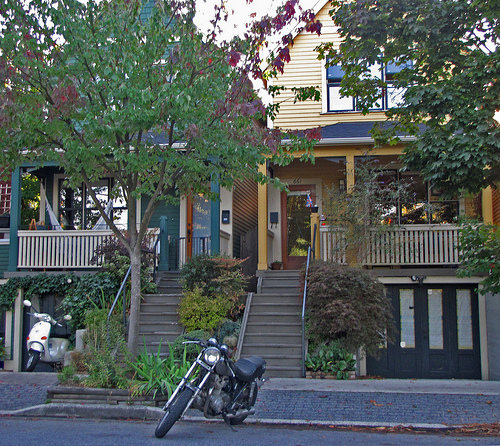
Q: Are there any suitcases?
A: No, there are no suitcases.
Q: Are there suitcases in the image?
A: No, there are no suitcases.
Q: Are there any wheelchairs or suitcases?
A: No, there are no suitcases or wheelchairs.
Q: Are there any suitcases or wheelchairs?
A: No, there are no suitcases or wheelchairs.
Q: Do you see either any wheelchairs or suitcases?
A: No, there are no suitcases or wheelchairs.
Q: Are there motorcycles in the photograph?
A: Yes, there is a motorcycle.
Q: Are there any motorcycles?
A: Yes, there is a motorcycle.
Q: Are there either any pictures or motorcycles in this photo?
A: Yes, there is a motorcycle.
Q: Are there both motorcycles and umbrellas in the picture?
A: No, there is a motorcycle but no umbrellas.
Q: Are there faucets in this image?
A: No, there are no faucets.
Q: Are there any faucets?
A: No, there are no faucets.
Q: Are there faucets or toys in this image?
A: No, there are no faucets or toys.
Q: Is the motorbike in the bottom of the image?
A: Yes, the motorbike is in the bottom of the image.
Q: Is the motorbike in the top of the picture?
A: No, the motorbike is in the bottom of the image.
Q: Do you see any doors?
A: Yes, there is a door.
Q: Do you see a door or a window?
A: Yes, there is a door.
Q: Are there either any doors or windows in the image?
A: Yes, there is a door.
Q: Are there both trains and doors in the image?
A: No, there is a door but no trains.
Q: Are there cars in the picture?
A: No, there are no cars.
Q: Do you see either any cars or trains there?
A: No, there are no cars or trains.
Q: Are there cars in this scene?
A: No, there are no cars.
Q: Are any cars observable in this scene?
A: No, there are no cars.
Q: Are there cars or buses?
A: No, there are no cars or buses.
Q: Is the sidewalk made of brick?
A: Yes, the sidewalk is made of brick.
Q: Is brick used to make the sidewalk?
A: Yes, the sidewalk is made of brick.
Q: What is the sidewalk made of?
A: The sidewalk is made of brick.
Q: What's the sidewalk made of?
A: The sidewalk is made of brick.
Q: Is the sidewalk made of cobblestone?
A: No, the sidewalk is made of brick.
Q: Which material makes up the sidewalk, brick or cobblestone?
A: The sidewalk is made of brick.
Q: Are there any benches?
A: No, there are no benches.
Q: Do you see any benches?
A: No, there are no benches.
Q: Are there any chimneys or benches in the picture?
A: No, there are no benches or chimneys.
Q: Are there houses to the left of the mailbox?
A: Yes, there is a house to the left of the mailbox.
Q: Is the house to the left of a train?
A: No, the house is to the left of the mailbox.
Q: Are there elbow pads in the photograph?
A: No, there are no elbow pads.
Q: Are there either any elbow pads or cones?
A: No, there are no elbow pads or cones.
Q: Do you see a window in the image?
A: Yes, there is a window.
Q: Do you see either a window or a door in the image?
A: Yes, there is a window.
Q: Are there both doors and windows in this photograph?
A: Yes, there are both a window and a door.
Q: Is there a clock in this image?
A: No, there are no clocks.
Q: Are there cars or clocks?
A: No, there are no clocks or cars.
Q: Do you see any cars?
A: No, there are no cars.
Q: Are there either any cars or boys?
A: No, there are no cars or boys.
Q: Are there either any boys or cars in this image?
A: No, there are no cars or boys.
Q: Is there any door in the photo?
A: Yes, there are doors.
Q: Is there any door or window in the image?
A: Yes, there are doors.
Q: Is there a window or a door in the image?
A: Yes, there are doors.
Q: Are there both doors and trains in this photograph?
A: No, there are doors but no trains.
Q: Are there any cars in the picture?
A: No, there are no cars.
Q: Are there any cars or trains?
A: No, there are no cars or trains.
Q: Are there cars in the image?
A: No, there are no cars.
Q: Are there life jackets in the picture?
A: No, there are no life jackets.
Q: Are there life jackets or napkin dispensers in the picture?
A: No, there are no life jackets or napkin dispensers.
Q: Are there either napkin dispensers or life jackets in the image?
A: No, there are no life jackets or napkin dispensers.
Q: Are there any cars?
A: No, there are no cars.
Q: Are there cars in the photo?
A: No, there are no cars.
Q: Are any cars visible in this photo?
A: No, there are no cars.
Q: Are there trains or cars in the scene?
A: No, there are no cars or trains.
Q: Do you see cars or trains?
A: No, there are no cars or trains.